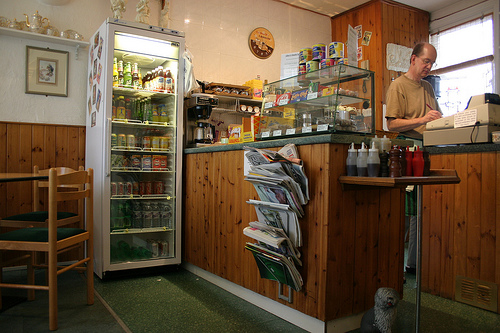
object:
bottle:
[412, 145, 425, 176]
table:
[341, 168, 461, 188]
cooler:
[80, 16, 182, 281]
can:
[152, 155, 168, 171]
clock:
[248, 27, 275, 60]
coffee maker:
[184, 94, 220, 149]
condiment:
[366, 141, 381, 178]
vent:
[455, 278, 497, 310]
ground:
[120, 291, 211, 330]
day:
[428, 27, 490, 124]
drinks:
[112, 92, 172, 125]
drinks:
[109, 133, 169, 151]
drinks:
[111, 179, 166, 197]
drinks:
[111, 201, 172, 231]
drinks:
[111, 238, 169, 263]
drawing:
[25, 45, 69, 97]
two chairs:
[2, 165, 94, 331]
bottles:
[346, 141, 380, 177]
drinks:
[111, 57, 174, 94]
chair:
[0, 168, 94, 332]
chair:
[0, 165, 86, 300]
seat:
[0, 227, 89, 251]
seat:
[1, 210, 79, 227]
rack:
[276, 158, 305, 303]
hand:
[425, 110, 443, 123]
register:
[420, 91, 500, 147]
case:
[254, 63, 376, 141]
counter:
[185, 133, 414, 333]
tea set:
[0, 10, 84, 42]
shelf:
[0, 25, 90, 61]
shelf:
[187, 91, 262, 116]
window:
[427, 14, 494, 116]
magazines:
[243, 144, 310, 292]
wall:
[6, 1, 296, 70]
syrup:
[345, 163, 381, 177]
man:
[387, 40, 444, 273]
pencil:
[426, 104, 433, 111]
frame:
[25, 87, 70, 98]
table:
[0, 173, 49, 181]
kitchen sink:
[422, 92, 500, 147]